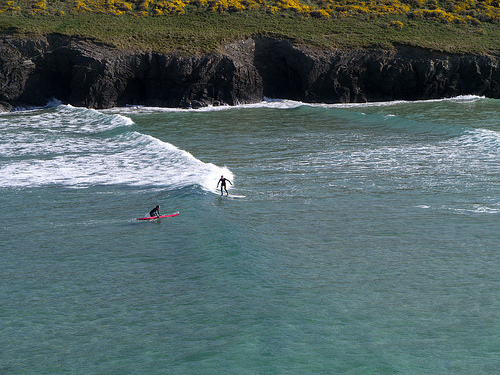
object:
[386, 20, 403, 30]
flowers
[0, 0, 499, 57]
ground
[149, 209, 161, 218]
wetsuit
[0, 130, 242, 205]
wave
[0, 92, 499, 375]
ocean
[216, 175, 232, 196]
person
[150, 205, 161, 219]
person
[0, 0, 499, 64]
grass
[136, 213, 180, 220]
surfboard